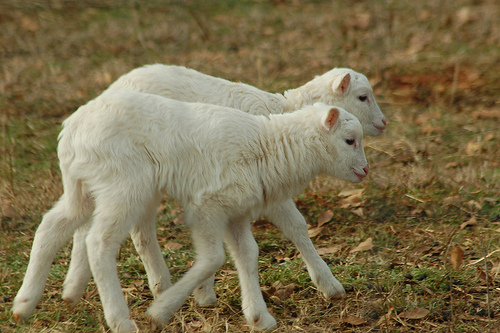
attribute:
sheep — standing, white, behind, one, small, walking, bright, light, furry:
[9, 88, 372, 327]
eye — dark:
[343, 136, 357, 147]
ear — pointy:
[322, 106, 341, 129]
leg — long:
[84, 198, 142, 331]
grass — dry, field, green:
[1, 1, 499, 330]